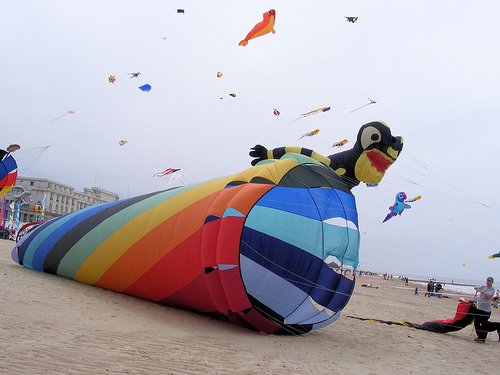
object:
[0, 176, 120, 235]
building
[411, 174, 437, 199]
ground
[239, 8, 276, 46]
building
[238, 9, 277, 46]
kite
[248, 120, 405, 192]
kite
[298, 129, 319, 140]
kite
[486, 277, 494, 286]
hat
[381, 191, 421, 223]
kite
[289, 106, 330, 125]
kites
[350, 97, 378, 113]
kites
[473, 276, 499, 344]
man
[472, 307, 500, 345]
pants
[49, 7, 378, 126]
kites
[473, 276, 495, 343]
bike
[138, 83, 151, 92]
kite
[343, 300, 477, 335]
kite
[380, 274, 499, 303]
ocean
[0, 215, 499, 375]
sand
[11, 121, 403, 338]
kite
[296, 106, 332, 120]
kite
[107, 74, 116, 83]
kite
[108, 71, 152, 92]
kites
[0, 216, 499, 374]
beach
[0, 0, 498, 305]
sky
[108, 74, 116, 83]
kite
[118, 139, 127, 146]
kite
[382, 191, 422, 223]
bird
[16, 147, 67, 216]
distance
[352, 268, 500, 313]
background